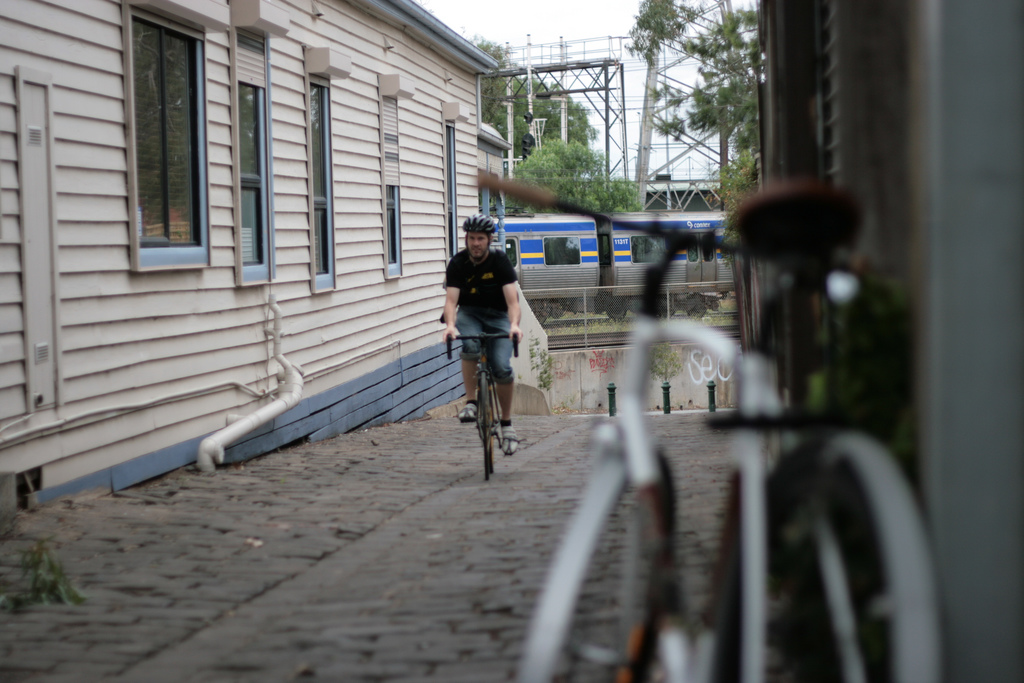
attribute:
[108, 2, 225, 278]
window — closest 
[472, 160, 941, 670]
bike — white  and blurry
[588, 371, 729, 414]
poles — short and black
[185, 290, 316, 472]
pipe — white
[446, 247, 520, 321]
shirt — black 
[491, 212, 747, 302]
train — blue, yellow and silver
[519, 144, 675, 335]
train car — sliver and blue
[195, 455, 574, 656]
bricks — red